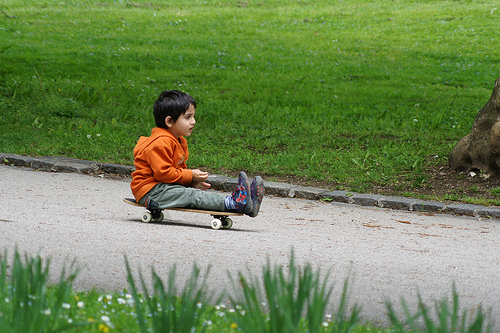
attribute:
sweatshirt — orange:
[129, 122, 194, 202]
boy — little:
[127, 84, 271, 221]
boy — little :
[136, 83, 205, 203]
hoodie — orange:
[127, 130, 187, 188]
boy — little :
[140, 86, 196, 201]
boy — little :
[141, 90, 199, 198]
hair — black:
[150, 84, 180, 114]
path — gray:
[19, 166, 499, 311]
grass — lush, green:
[32, 27, 435, 78]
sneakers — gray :
[235, 161, 266, 220]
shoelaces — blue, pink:
[226, 183, 246, 204]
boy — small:
[122, 81, 206, 190]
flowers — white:
[158, 10, 288, 83]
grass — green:
[87, 11, 351, 68]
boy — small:
[140, 85, 207, 177]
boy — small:
[131, 90, 203, 199]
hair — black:
[152, 90, 185, 117]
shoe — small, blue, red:
[227, 169, 254, 218]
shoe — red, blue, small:
[250, 175, 269, 210]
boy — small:
[136, 85, 196, 205]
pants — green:
[141, 175, 236, 205]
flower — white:
[400, 107, 421, 128]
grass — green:
[343, 95, 405, 153]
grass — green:
[398, 20, 472, 74]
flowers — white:
[374, 50, 463, 141]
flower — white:
[71, 295, 91, 310]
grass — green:
[46, 289, 160, 329]